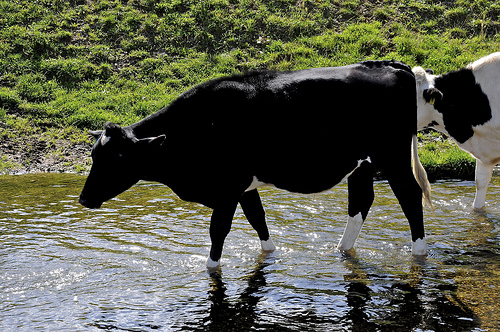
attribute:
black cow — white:
[49, 48, 430, 251]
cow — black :
[39, 41, 484, 269]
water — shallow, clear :
[5, 176, 486, 329]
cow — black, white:
[76, 61, 431, 271]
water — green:
[1, 157, 497, 330]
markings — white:
[210, 145, 430, 269]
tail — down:
[394, 57, 433, 198]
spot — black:
[431, 67, 491, 143]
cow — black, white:
[411, 49, 498, 210]